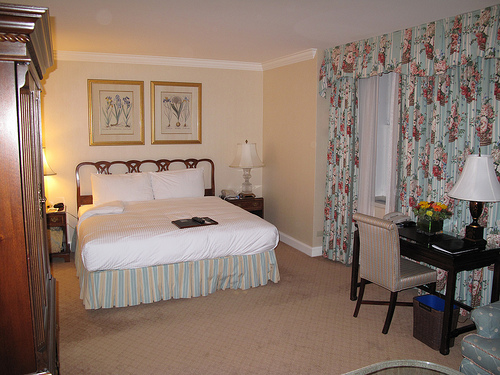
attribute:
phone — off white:
[375, 209, 407, 225]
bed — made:
[75, 158, 282, 310]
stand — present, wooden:
[222, 195, 265, 218]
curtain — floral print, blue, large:
[320, 3, 499, 315]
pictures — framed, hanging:
[87, 78, 203, 145]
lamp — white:
[229, 138, 266, 200]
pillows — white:
[92, 167, 204, 203]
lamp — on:
[39, 146, 59, 206]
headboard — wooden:
[76, 157, 216, 207]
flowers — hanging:
[414, 200, 450, 220]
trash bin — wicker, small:
[412, 292, 457, 350]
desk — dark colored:
[350, 217, 499, 345]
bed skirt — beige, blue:
[76, 240, 281, 310]